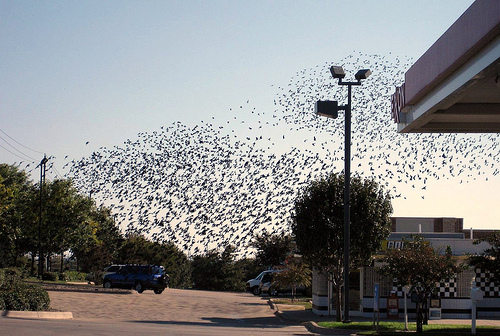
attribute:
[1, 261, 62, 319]
shrub — large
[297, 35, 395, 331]
post — tall, black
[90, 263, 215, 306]
suv — blue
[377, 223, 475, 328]
wall — black and white, checked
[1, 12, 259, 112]
sky — cloudless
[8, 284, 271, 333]
roadway — paved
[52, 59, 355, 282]
birds — black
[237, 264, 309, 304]
van — white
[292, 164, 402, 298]
tree — round, green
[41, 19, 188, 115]
sky — clear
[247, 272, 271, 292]
van — white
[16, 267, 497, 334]
parking lot — pictured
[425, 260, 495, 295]
checks — black, white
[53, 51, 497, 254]
bird flock — flying, large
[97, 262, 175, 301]
vehicle — blue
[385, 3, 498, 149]
roof — overhanging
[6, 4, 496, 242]
sky — blue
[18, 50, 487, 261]
birds — airborne